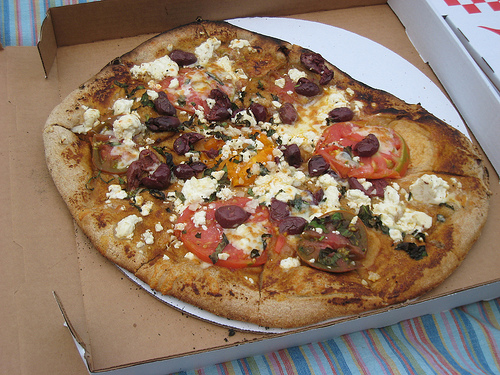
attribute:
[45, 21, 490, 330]
pizza — circle, burnt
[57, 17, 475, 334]
plate — white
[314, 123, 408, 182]
tomato — green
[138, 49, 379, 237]
olives — black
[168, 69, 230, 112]
pepper — red, yellow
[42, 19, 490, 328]
crust — burnt, burned, thick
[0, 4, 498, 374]
box — open, cardboard, white, red, circle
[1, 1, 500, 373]
cloth — striped, white, blue, red, green, colorful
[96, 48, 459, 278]
toppings — green